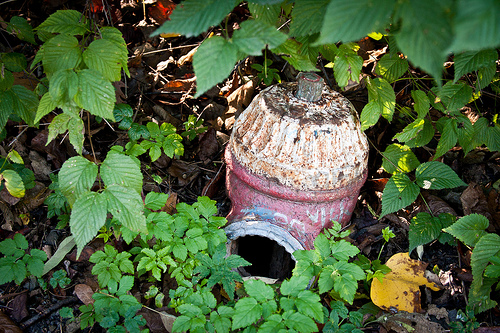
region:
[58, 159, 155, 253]
these are leafs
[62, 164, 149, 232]
the leaf is green in color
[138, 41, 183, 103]
these are dry leaflets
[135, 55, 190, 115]
the dry leaflets are brown in color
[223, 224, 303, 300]
this is a hole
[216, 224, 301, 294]
the hole is round in shape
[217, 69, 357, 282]
this is a metallic pipe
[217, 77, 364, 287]
this is a dry water pipe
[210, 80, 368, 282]
the dry water pipe is white and red in color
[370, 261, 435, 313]
this is a yellow dry leaflet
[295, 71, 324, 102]
a bolt on the fire hydrant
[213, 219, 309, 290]
an open hole on the fire hydrant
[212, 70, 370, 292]
an old red and white fire hydrant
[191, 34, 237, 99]
a green leaf on a plant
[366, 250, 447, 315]
a yellow leaf on the ground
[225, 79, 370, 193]
the top of a fire hydrant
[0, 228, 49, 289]
a small green plant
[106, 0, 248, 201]
brown leaves on the ground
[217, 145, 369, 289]
the body of a fire hydrant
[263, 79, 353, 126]
dirt on top of a fire hydrant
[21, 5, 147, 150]
green leaves on plant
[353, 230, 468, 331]
yellow decaying leaf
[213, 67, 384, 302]
old firehydrant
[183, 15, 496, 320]
abandoned firehydrant with fading paint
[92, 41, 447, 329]
healthy plants growing amongst firehydrant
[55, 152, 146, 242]
plant with 4 leaves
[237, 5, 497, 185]
light coming through green plants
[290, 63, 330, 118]
rusty screw on firehydrant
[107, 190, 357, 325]
green young growing plants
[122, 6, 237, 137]
dead leaves on ground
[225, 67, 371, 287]
Old fire hydrant in the ground.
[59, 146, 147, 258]
Four green leaves on a thin branch.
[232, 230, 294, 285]
Hole in the front of a fire hydrant.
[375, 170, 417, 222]
Green leaf by a fire hydrant.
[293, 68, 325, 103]
Top part of a fire hydrant.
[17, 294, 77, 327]
Small twig on the ground.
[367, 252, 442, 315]
Yellow leaf on the ground.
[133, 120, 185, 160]
Group of small green leaves.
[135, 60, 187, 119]
Brown leaves on the ground.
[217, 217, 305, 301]
Round hole on front of fire hydrant.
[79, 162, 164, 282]
these are some leaves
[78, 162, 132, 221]
the leaves are green in color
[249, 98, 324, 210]
the object is metallic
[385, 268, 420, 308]
this is a dry leaf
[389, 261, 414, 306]
the dry leaf is yellow in color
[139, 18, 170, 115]
these are some twigs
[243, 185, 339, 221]
this object is red in color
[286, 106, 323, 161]
this object is made of stone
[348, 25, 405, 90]
there are sunlit leaves